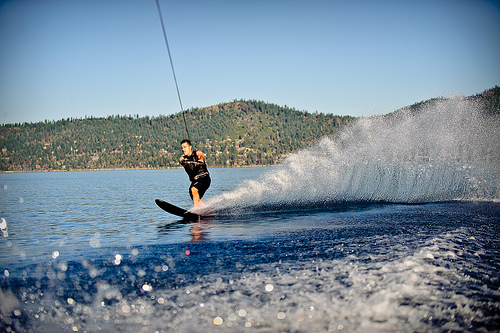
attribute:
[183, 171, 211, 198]
shorts — black, cotton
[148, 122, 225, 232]
man — cable-skiing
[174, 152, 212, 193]
life jacket — black, padded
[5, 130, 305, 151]
trees — green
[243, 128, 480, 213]
splashing — water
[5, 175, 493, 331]
water — blue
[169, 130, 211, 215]
man — cable-skiing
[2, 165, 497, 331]
lake — blue 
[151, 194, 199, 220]
waterboard — black